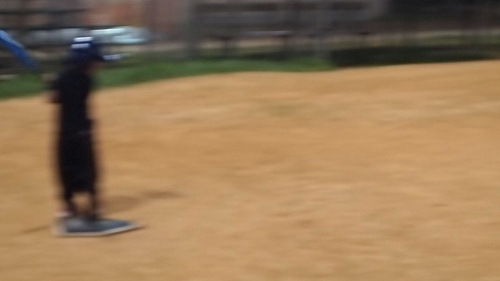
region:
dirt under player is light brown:
[1, 55, 498, 279]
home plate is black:
[53, 212, 145, 240]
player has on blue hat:
[63, 27, 120, 64]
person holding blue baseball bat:
[1, 29, 56, 101]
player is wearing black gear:
[48, 67, 98, 199]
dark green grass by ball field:
[1, 58, 332, 98]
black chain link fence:
[0, 0, 499, 65]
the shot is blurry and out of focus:
[0, 1, 498, 279]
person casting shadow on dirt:
[10, 181, 180, 245]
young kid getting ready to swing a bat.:
[5, 11, 143, 242]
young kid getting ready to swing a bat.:
[0, 20, 147, 245]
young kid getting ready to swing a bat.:
[2, 20, 139, 245]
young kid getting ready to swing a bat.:
[5, 15, 145, 240]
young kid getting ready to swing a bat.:
[5, 15, 145, 235]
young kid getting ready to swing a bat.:
[6, 15, 136, 240]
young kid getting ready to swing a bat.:
[5, 22, 142, 237]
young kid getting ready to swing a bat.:
[5, 27, 135, 237]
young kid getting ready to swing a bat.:
[7, 30, 139, 236]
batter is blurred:
[1, 19, 138, 240]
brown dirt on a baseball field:
[4, 58, 499, 278]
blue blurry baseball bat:
[1, 32, 46, 79]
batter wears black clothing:
[38, 48, 122, 225]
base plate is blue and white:
[53, 210, 142, 244]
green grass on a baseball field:
[6, 52, 333, 106]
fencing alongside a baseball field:
[1, 1, 498, 53]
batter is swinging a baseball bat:
[1, 26, 112, 226]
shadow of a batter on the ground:
[71, 184, 199, 220]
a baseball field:
[1, 60, 496, 277]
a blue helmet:
[65, 33, 119, 65]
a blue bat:
[1, 25, 52, 90]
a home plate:
[60, 210, 147, 239]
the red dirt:
[1, 65, 498, 279]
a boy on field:
[1, 30, 124, 227]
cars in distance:
[21, 19, 149, 43]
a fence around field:
[1, 0, 498, 63]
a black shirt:
[47, 58, 98, 127]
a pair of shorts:
[49, 124, 101, 196]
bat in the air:
[2, 23, 51, 75]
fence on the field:
[0, 1, 432, 82]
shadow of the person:
[96, 168, 181, 234]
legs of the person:
[53, 185, 110, 237]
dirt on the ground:
[2, 58, 495, 267]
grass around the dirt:
[5, 38, 480, 94]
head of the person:
[58, 31, 105, 61]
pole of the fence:
[185, 3, 205, 60]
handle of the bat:
[20, 48, 57, 103]